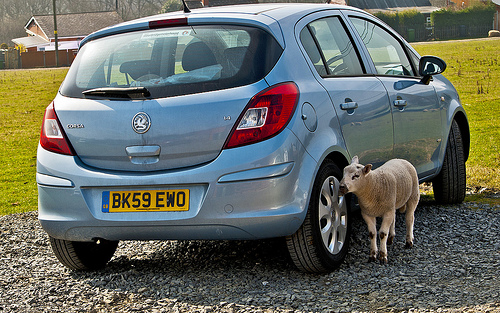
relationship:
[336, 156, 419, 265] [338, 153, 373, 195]
lamb has head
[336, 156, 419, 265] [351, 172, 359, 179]
lamb has eye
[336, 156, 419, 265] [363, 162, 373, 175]
lamb has ear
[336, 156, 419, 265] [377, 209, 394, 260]
lamb has front leg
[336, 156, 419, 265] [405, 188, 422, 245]
lamb has hind leg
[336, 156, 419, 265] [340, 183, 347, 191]
lamb has nose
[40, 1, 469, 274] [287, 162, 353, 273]
car has wheel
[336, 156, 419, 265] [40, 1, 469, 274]
lamb next to car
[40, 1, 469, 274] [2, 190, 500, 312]
car on top of gravel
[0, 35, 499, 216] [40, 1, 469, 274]
field behind car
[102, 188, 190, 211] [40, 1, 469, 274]
license plate on top of car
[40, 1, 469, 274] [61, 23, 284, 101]
car has back window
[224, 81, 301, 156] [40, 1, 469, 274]
taillight on top of car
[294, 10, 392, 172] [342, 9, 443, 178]
door next to door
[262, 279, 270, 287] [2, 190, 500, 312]
rock on top of gravel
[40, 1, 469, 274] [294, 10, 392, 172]
car has door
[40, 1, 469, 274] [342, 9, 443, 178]
car has door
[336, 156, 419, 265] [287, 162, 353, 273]
lamb next to wheel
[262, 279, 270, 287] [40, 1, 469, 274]
rock beneath car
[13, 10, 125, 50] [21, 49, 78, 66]
house behind fence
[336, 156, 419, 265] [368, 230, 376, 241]
lamb has smudge